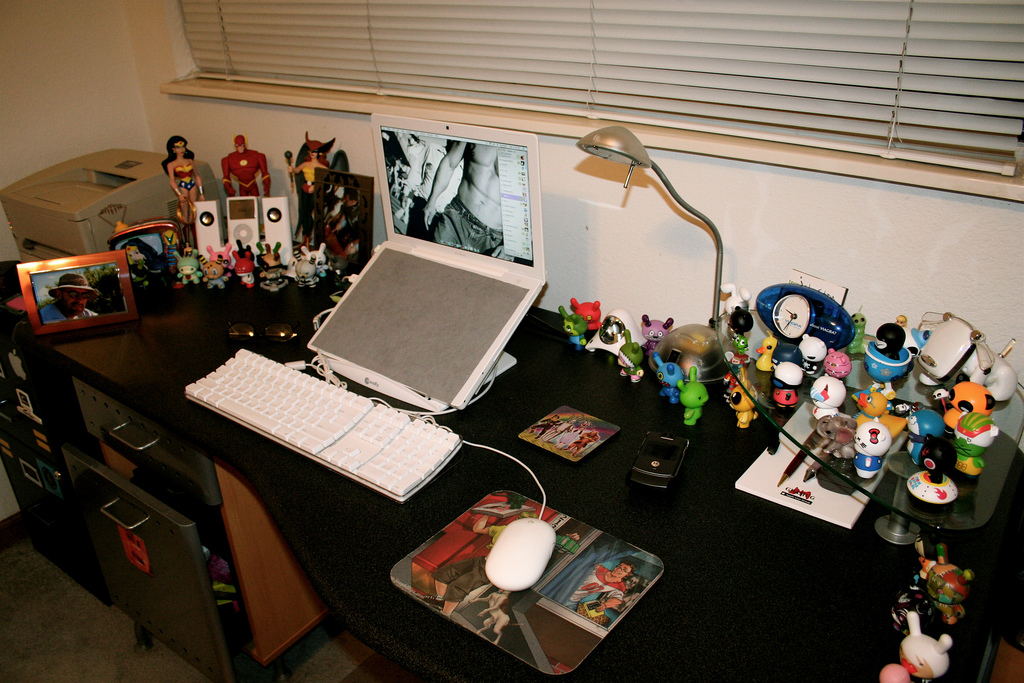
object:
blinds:
[158, 0, 1024, 204]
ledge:
[159, 68, 1022, 206]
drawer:
[61, 446, 261, 681]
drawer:
[68, 375, 224, 508]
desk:
[0, 237, 1024, 683]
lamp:
[577, 125, 724, 386]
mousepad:
[384, 487, 664, 675]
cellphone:
[632, 431, 690, 476]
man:
[39, 272, 99, 323]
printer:
[0, 148, 219, 266]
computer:
[307, 113, 546, 415]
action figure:
[676, 365, 709, 426]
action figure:
[852, 416, 891, 479]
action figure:
[558, 305, 588, 351]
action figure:
[569, 297, 604, 330]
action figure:
[953, 412, 999, 476]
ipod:
[225, 196, 260, 256]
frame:
[16, 248, 137, 335]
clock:
[755, 283, 856, 352]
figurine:
[654, 352, 686, 403]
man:
[424, 139, 517, 262]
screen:
[380, 127, 536, 269]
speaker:
[262, 196, 294, 263]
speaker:
[195, 201, 222, 260]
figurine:
[906, 434, 958, 505]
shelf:
[715, 310, 1024, 531]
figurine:
[906, 408, 945, 466]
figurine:
[822, 348, 850, 378]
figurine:
[799, 334, 827, 375]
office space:
[0, 0, 1024, 682]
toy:
[616, 329, 644, 382]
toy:
[641, 314, 674, 359]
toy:
[729, 365, 757, 430]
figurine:
[810, 375, 846, 421]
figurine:
[848, 304, 868, 354]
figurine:
[718, 283, 751, 315]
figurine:
[770, 359, 805, 409]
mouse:
[485, 518, 556, 591]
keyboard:
[186, 349, 463, 502]